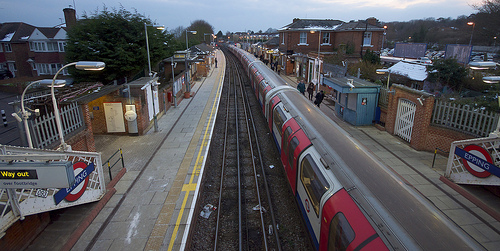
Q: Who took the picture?
A: The photographer.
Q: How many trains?
A: One.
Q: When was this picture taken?
A: At dusk.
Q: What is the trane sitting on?
A: The tracks.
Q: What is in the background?
A: Buildings.